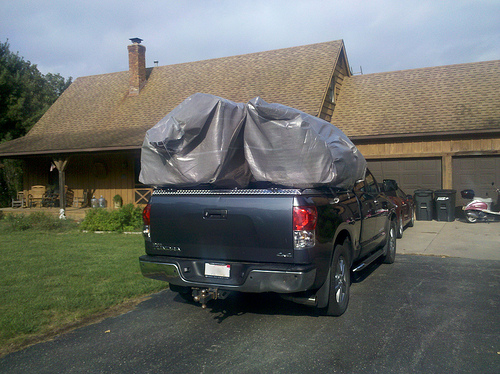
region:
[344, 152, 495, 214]
two dark gray garage doors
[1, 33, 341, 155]
gray tiled roof with a red brick chimney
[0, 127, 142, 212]
front porch area of a home with a column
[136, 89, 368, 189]
gray tarp over cargo in a pick up truck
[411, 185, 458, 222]
two trash barrels in front of a garage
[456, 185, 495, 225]
motor scooter in front of a garage door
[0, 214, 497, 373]
dark gray paved driveway in front of a garage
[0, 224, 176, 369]
green grass in a front yard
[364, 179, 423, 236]
dark car parked in front of a garage door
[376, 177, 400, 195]
black side view mirror on a pick up truck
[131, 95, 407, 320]
truck parked in driveway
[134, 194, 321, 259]
red brakelights on back of truck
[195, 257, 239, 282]
white license plate on back of truck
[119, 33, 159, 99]
brick chimney on top of room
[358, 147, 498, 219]
two brown garage doors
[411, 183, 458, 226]
two green trash cans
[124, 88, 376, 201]
grey pastic covered cargo on back of truck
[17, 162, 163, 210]
wood panelled house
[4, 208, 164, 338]
green grass covered lawn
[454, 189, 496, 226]
grey and maroon motorcycle parked in front of garage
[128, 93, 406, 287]
truck parked in a driveway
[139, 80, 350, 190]
truck loading a covered object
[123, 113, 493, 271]
truck parked behind a car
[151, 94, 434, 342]
truck parked in front of a house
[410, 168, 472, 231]
trash cans standing near the garage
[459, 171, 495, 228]
a bike parked in front of a garabe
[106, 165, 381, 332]
a truck designed with blue exterior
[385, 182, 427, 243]
a car parked in front of a truck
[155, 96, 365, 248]
a covered object loaded onto a truck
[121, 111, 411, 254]
a grey tarp covering a big object.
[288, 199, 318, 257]
a taillight on the truck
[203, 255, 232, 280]
a tag on the back of the truck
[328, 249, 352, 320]
a tire on the truck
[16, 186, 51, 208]
cairs sitting on the porch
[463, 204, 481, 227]
a tire on the scooter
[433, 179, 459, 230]
a garbage can next to the house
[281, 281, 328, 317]
a muffler on the truck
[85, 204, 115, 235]
bushes growing in front of the house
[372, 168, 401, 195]
a mirror on the side of the truck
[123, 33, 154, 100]
a chimney on the roof of the house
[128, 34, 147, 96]
brick chimney on house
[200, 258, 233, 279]
license plate on back of blue truck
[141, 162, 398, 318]
navy blue truck in driveway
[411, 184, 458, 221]
two waste bins in front of garage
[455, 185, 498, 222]
motorcycle in front of garage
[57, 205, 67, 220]
concrete garden statue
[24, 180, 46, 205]
patio chair on front porch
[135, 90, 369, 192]
two-pieces of covered furniture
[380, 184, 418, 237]
red car in front of truck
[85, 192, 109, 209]
two water jugs on front porch